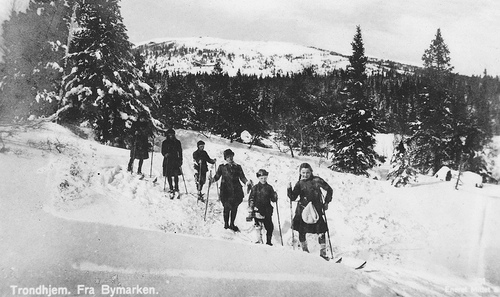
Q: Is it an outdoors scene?
A: Yes, it is outdoors.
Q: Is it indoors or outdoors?
A: It is outdoors.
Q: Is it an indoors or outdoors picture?
A: It is outdoors.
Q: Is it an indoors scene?
A: No, it is outdoors.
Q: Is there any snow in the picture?
A: Yes, there is snow.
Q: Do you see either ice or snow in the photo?
A: Yes, there is snow.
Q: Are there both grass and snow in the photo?
A: No, there is snow but no grass.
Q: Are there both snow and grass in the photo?
A: No, there is snow but no grass.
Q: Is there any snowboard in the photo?
A: No, there are no snowboards.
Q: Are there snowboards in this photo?
A: No, there are no snowboards.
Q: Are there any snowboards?
A: No, there are no snowboards.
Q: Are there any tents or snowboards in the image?
A: No, there are no snowboards or tents.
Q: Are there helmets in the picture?
A: No, there are no helmets.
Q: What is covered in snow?
A: The mountain is covered in snow.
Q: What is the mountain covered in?
A: The mountain is covered in snow.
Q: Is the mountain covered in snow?
A: Yes, the mountain is covered in snow.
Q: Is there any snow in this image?
A: Yes, there is snow.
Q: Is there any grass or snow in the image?
A: Yes, there is snow.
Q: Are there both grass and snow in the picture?
A: No, there is snow but no grass.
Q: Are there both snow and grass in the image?
A: No, there is snow but no grass.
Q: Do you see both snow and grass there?
A: No, there is snow but no grass.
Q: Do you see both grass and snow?
A: No, there is snow but no grass.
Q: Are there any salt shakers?
A: No, there are no salt shakers.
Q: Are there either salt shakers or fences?
A: No, there are no salt shakers or fences.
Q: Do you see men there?
A: No, there are no men.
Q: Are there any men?
A: No, there are no men.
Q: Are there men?
A: No, there are no men.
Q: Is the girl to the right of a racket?
A: No, the girl is to the right of a skier.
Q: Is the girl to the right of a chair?
A: No, the girl is to the right of a skier.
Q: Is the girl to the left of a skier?
A: No, the girl is to the right of a skier.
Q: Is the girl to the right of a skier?
A: Yes, the girl is to the right of a skier.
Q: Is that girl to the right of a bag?
A: No, the girl is to the right of a skier.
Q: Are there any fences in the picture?
A: No, there are no fences.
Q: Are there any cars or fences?
A: No, there are no fences or cars.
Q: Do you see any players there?
A: No, there are no players.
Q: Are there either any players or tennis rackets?
A: No, there are no players or tennis rackets.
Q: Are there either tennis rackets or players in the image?
A: No, there are no players or tennis rackets.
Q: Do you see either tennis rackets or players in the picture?
A: No, there are no players or tennis rackets.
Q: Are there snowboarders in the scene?
A: No, there are no snowboarders.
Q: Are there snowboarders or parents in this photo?
A: No, there are no snowboarders or parents.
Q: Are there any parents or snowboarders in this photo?
A: No, there are no snowboarders or parents.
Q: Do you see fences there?
A: No, there are no fences.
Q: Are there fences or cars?
A: No, there are no fences or cars.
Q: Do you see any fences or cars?
A: No, there are no fences or cars.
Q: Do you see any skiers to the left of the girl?
A: Yes, there is a skier to the left of the girl.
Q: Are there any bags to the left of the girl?
A: No, there is a skier to the left of the girl.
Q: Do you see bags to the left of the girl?
A: No, there is a skier to the left of the girl.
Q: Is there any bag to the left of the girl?
A: No, there is a skier to the left of the girl.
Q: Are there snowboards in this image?
A: No, there are no snowboards.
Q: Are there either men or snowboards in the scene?
A: No, there are no snowboards or men.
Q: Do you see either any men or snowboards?
A: No, there are no snowboards or men.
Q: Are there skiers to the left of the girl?
A: Yes, there is a skier to the left of the girl.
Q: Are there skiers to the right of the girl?
A: No, the skier is to the left of the girl.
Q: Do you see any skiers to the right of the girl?
A: No, the skier is to the left of the girl.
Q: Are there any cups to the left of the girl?
A: No, there is a skier to the left of the girl.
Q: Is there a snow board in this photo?
A: No, there are no snowboards.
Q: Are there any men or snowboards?
A: No, there are no snowboards or men.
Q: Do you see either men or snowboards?
A: No, there are no snowboards or men.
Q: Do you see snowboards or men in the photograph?
A: No, there are no snowboards or men.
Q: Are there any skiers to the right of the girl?
A: No, the skier is to the left of the girl.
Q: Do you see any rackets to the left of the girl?
A: No, there is a skier to the left of the girl.